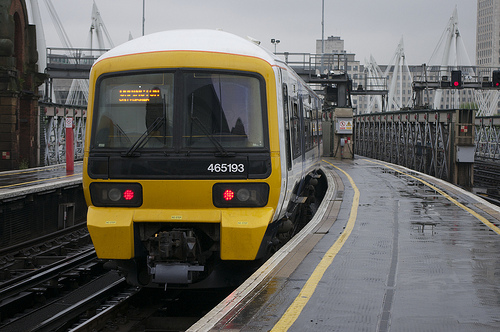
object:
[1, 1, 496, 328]
day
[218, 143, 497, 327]
ground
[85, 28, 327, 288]
train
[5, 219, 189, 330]
tracks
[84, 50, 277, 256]
front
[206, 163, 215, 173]
number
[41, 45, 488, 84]
bridge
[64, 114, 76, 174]
pole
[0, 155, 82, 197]
platform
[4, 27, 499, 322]
train station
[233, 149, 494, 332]
platform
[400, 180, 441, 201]
puddle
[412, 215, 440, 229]
puddle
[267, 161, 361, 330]
stripe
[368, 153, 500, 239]
stripe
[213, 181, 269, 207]
front light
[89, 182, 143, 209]
front light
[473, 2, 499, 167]
building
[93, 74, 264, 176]
window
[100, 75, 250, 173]
reflection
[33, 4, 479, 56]
sky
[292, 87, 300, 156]
windiw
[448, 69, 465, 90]
traffic light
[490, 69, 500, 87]
traffic light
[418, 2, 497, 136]
background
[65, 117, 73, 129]
sign